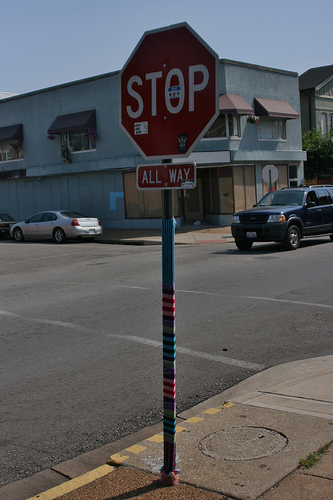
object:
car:
[9, 209, 102, 243]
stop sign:
[117, 21, 220, 160]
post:
[161, 156, 178, 488]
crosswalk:
[0, 276, 333, 372]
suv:
[231, 183, 333, 254]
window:
[69, 129, 90, 151]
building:
[0, 61, 307, 229]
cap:
[200, 426, 288, 462]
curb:
[31, 397, 236, 500]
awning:
[254, 97, 299, 119]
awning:
[219, 93, 255, 116]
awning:
[47, 109, 96, 134]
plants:
[60, 142, 70, 164]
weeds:
[298, 443, 329, 475]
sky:
[0, 1, 333, 104]